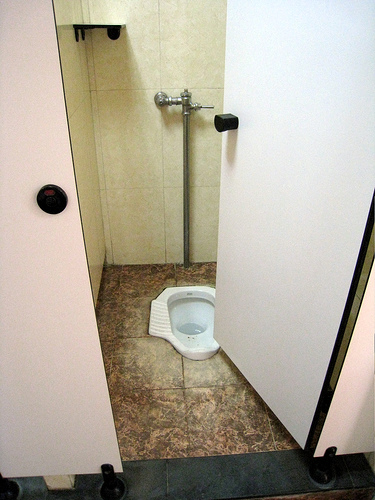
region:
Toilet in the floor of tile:
[137, 272, 256, 360]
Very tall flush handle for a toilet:
[154, 72, 220, 278]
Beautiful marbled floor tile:
[124, 366, 216, 437]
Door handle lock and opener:
[28, 180, 85, 233]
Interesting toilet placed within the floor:
[143, 278, 228, 381]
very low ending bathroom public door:
[210, 70, 361, 405]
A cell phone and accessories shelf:
[69, 15, 165, 80]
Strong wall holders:
[62, 444, 154, 492]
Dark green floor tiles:
[151, 463, 284, 490]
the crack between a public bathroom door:
[321, 228, 363, 427]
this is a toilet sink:
[149, 281, 226, 350]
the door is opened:
[222, 1, 370, 425]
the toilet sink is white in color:
[167, 301, 213, 339]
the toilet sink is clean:
[169, 302, 217, 343]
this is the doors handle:
[213, 108, 237, 132]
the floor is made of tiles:
[124, 368, 230, 455]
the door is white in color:
[240, 2, 370, 359]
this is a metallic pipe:
[163, 90, 199, 276]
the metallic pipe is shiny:
[154, 93, 203, 272]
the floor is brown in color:
[130, 377, 226, 439]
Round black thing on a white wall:
[33, 182, 72, 216]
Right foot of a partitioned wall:
[310, 436, 341, 495]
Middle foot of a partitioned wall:
[91, 462, 127, 498]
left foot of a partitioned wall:
[2, 470, 23, 498]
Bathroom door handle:
[210, 112, 241, 135]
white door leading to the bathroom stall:
[210, 4, 373, 463]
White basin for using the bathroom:
[140, 276, 223, 359]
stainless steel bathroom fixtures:
[149, 81, 217, 270]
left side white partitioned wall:
[1, 0, 139, 478]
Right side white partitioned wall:
[310, 261, 372, 460]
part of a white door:
[288, 218, 342, 290]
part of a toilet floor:
[175, 406, 232, 459]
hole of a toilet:
[181, 310, 199, 331]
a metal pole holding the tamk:
[177, 180, 196, 264]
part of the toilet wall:
[95, 65, 142, 143]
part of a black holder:
[90, 460, 121, 498]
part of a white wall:
[14, 351, 67, 446]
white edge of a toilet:
[160, 339, 205, 356]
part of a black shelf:
[81, 10, 130, 47]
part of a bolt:
[200, 102, 211, 114]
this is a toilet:
[151, 285, 210, 352]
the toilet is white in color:
[180, 335, 207, 351]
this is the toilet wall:
[94, 56, 157, 253]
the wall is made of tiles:
[102, 219, 174, 259]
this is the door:
[245, 15, 307, 362]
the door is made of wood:
[252, 356, 321, 383]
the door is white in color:
[260, 346, 305, 394]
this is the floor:
[128, 363, 234, 438]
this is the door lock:
[212, 105, 238, 137]